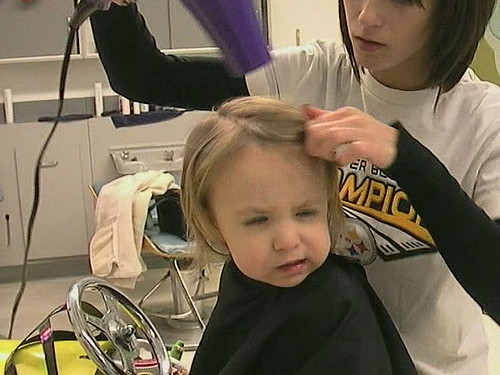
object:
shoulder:
[309, 260, 370, 311]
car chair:
[0, 274, 187, 375]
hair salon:
[1, 1, 500, 375]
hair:
[179, 96, 344, 271]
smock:
[90, 171, 180, 289]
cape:
[187, 257, 419, 375]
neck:
[359, 55, 436, 90]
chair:
[86, 175, 216, 331]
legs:
[166, 266, 206, 329]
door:
[14, 138, 92, 260]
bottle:
[3, 88, 15, 123]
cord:
[8, 30, 76, 353]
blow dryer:
[68, 0, 270, 74]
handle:
[35, 160, 59, 168]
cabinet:
[0, 21, 273, 266]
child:
[176, 96, 418, 375]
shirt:
[242, 36, 500, 374]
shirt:
[83, 1, 500, 328]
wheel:
[64, 276, 170, 375]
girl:
[85, 0, 496, 373]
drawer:
[12, 145, 90, 261]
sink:
[111, 147, 194, 173]